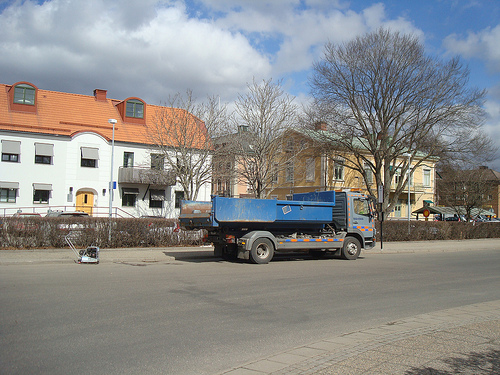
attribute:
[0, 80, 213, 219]
building — white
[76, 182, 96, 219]
yellow — door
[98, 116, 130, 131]
lantern — tall 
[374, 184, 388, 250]
sign — small 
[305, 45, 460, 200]
tree — part